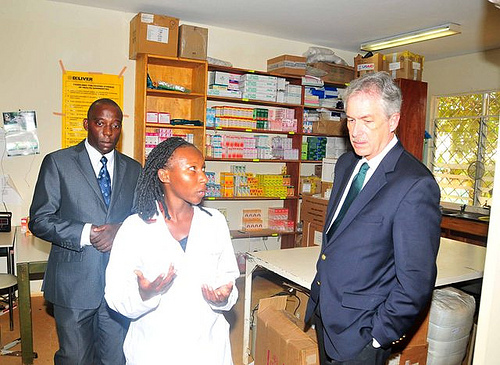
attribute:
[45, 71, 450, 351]
people — standing inside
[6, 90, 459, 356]
people — standing inside, three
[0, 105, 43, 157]
poster — small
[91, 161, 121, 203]
tie — blue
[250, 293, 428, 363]
cardboard box — partially opened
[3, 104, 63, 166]
poster — small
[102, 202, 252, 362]
coat — white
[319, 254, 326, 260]
button — gold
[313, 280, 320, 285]
button — gold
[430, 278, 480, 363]
bundle — white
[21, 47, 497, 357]
men — wearing ties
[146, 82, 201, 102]
shelf — brown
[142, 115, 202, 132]
shelf — brown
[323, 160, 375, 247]
blue tie — dark blue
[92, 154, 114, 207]
blue tie — dark blue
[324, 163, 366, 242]
neck tie — turquoise blue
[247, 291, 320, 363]
box — brown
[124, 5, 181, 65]
box — cardboard, open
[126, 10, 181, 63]
box — cardboard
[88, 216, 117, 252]
hands — clasped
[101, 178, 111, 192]
spots — white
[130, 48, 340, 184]
bookshelves — wooden